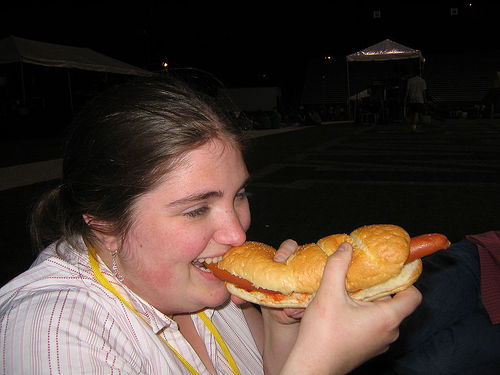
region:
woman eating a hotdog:
[8, 56, 449, 368]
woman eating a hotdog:
[5, 46, 486, 348]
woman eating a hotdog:
[5, 51, 456, 369]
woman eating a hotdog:
[11, 49, 458, 373]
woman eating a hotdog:
[14, 39, 464, 371]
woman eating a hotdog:
[5, 36, 450, 363]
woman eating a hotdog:
[2, 48, 494, 370]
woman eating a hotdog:
[15, 68, 460, 373]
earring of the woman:
[108, 249, 120, 280]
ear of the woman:
[84, 209, 120, 252]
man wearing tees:
[408, 78, 424, 103]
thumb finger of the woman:
[321, 242, 353, 303]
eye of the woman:
[179, 203, 212, 222]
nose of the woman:
[216, 217, 247, 247]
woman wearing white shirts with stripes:
[15, 288, 127, 373]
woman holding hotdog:
[226, 241, 442, 298]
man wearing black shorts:
[408, 103, 424, 110]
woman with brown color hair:
[85, 96, 190, 156]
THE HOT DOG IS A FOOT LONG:
[182, 206, 464, 311]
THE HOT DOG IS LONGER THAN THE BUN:
[393, 201, 453, 276]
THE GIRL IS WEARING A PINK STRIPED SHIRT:
[0, 230, 296, 371]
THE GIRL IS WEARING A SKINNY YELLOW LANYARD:
[76, 237, 252, 372]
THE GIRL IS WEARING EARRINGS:
[96, 235, 139, 297]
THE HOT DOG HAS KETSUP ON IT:
[192, 215, 473, 308]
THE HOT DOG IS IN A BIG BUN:
[210, 220, 435, 315]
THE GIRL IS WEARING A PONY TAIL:
[15, 140, 86, 271]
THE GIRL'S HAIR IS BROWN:
[25, 66, 251, 297]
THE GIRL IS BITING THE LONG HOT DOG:
[192, 240, 274, 311]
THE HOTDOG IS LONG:
[191, 210, 452, 321]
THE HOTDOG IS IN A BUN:
[195, 222, 456, 307]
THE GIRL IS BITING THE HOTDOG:
[185, 240, 261, 315]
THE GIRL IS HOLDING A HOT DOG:
[181, 215, 489, 346]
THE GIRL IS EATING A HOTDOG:
[197, 222, 459, 324]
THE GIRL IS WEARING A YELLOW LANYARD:
[66, 226, 258, 372]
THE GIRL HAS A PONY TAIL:
[27, 55, 247, 261]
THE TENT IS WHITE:
[332, 20, 433, 70]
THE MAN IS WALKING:
[395, 56, 433, 151]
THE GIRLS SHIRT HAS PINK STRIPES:
[1, 228, 268, 373]